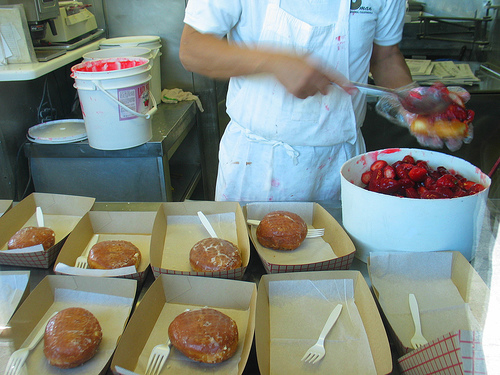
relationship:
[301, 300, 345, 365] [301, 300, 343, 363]
fork made of fork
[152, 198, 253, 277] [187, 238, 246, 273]
food tray has a donut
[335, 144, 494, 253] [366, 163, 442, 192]
bucket contains strawberries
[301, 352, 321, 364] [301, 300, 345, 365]
tines on fork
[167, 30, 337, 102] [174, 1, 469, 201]
arm of man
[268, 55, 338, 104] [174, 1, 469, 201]
hand of a man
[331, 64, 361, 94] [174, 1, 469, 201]
finger of a man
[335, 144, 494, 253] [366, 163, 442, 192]
bucket has strawberries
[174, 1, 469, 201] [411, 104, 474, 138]
man making donut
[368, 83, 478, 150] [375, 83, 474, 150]
glove made of glove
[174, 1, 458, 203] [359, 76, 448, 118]
man holding spoon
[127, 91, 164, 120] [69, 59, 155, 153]
handle on bucket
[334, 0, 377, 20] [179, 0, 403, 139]
emblem on shirt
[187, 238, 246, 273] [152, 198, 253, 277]
donut in food tray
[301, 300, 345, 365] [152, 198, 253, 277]
fork in food tray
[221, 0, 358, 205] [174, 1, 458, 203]
apron of man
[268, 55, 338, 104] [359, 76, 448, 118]
hand holding spoon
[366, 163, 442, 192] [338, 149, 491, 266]
strawberries are in pail